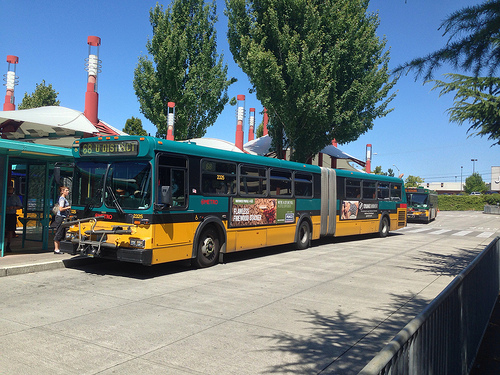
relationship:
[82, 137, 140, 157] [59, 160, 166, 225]
sign over windshield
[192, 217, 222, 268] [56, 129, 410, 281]
tire on bus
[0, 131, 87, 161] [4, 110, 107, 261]
blue trim on building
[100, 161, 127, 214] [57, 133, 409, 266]
wiper on bus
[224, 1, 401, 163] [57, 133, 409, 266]
large tree beside bus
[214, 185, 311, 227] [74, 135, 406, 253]
advertisement on side of bus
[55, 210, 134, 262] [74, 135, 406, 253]
bike rack on front of bus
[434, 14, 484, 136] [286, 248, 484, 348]
tree has shadow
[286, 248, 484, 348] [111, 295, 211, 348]
shadow on ground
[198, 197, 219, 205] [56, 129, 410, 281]
lettering on side of bus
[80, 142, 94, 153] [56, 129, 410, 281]
number on bus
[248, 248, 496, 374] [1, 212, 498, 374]
tree shdows on pavement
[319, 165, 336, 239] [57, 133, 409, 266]
connector binds bus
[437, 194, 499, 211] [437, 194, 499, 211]
bushes are bushes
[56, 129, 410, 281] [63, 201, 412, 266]
bus has yellow bottom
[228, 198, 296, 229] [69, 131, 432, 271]
advertisement on bus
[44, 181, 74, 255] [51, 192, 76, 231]
woman wearing shirt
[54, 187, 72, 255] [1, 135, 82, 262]
woman at bus station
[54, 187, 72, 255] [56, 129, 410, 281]
woman waiting at bus